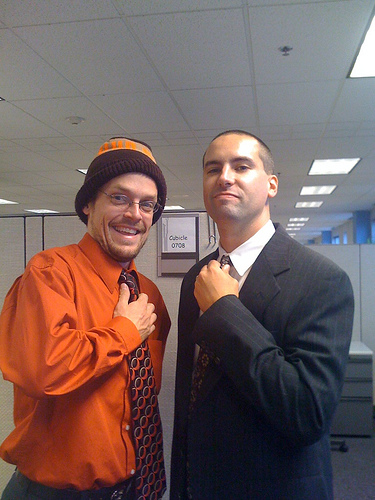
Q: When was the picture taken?
A: Daytime.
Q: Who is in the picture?
A: Men.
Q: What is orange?
A: Shirt.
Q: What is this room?
A: Office.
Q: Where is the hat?
A: Head.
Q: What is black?
A: Suit.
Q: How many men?
A: Two.